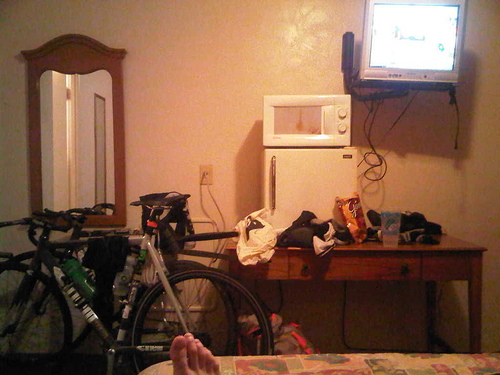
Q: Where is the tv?
A: On a shelf.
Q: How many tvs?
A: One.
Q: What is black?
A: Bike.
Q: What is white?
A: Microwave.